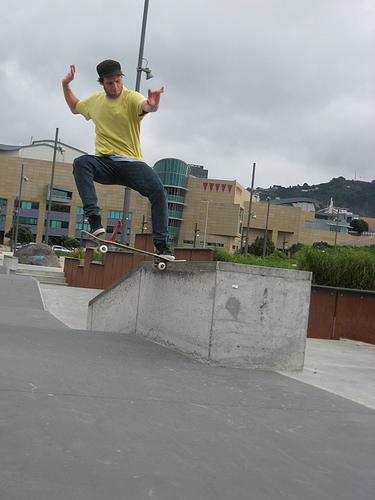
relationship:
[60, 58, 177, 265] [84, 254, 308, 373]
man near ramp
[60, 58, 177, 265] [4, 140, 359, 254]
man backed by buildings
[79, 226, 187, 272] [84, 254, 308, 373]
skateboard on ramp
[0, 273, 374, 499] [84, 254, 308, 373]
path with ramp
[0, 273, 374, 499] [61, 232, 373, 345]
path with wall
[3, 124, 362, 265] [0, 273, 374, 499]
buildings beyond path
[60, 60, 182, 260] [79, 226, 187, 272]
man on skateboard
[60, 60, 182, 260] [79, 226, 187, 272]
man doing tricks on skateboard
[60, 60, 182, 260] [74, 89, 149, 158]
man wearing shirt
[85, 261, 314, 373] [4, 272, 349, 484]
wall by path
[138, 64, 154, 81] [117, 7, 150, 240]
light hanging off pole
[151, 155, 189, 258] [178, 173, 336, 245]
building between building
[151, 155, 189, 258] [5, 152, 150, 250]
building between building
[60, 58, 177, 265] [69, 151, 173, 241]
man wearing jeans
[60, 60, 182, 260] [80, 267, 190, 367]
man in air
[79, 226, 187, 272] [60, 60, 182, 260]
skateboard under man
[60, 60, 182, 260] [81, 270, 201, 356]
man in air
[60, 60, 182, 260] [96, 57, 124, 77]
man wearing a cap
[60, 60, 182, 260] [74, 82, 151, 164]
man wearing a shirt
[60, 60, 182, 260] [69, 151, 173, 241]
man wearing jeans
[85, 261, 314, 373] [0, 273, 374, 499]
wall by path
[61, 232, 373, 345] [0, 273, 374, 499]
wall by path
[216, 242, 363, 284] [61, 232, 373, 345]
shrubbery behind wall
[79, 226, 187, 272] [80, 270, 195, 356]
skateboard in midair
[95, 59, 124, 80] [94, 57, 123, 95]
hat on head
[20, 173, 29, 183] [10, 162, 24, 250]
light on pole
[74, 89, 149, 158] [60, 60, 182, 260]
shirt on man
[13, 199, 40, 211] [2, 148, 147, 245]
windows in building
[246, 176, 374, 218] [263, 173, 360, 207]
hills in distance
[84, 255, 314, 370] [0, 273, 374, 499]
block on path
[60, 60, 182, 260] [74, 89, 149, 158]
man in shirt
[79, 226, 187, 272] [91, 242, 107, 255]
skateboard with wheels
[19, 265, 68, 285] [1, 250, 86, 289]
steps between walls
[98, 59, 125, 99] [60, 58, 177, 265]
head of man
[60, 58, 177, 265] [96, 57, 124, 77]
man wearing cap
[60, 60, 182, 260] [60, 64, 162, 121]
man with arms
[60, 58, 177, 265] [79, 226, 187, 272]
man doing trick on skateboard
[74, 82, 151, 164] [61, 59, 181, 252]
shirt on boy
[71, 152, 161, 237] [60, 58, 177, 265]
jeans on man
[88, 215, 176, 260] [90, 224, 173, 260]
high tops with soles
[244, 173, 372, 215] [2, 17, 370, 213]
hills in background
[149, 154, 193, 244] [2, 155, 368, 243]
center in building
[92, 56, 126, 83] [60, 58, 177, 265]
hat on man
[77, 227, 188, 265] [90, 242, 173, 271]
skateboard with wheels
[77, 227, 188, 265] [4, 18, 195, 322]
skateboard in air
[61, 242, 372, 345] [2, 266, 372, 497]
wall along skate park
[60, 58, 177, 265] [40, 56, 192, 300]
man doing trick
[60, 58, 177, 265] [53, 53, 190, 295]
man doing trick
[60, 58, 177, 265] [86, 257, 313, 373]
man grinding block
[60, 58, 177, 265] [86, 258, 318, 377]
man grinding concrete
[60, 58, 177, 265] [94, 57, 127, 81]
man wearing hat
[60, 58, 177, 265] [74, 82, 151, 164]
man wearing shirt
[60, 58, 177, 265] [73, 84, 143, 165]
man wearing t-shirt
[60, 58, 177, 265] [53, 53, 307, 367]
man doing trick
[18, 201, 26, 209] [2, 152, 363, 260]
window on building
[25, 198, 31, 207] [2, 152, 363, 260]
window on building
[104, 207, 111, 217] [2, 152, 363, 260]
window on building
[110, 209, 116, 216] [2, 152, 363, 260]
window on building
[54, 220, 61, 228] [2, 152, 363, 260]
window on building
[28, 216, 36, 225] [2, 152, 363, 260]
window on building